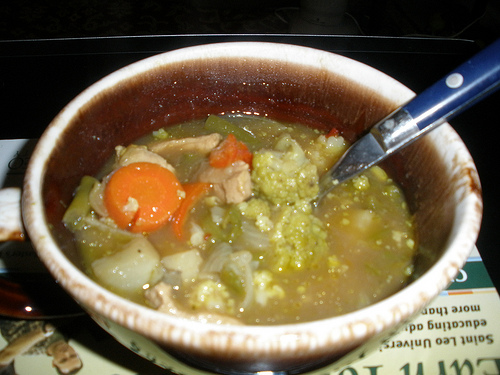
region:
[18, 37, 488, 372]
brown and white ceramic bowl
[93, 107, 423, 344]
vegetable soup in a bowl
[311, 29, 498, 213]
blue spoon in the soup bowl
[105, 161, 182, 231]
orange carrot slice in soup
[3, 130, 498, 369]
magazine underneath soup bowl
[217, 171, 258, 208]
chunk of chicken in soup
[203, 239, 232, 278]
white cooked onion in soup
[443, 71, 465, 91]
decorative silver circle on spoon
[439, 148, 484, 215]
brown streaks in white ceramic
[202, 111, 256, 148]
green bean in soup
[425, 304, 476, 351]
Black colored writings on a newspater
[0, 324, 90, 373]
Picture of a man with short hair on a newspaper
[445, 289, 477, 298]
Brown colored line mark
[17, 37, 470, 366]
Bowl of food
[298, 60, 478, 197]
Spoon inside the bowl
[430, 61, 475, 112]
A white dot on the handle of the spoon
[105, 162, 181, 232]
Piece of carrot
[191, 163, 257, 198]
Piece of meat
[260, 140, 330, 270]
Pieces of vegetable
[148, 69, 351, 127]
Brown colored portion of the bown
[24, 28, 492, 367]
a bowl of soup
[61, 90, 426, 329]
soup of vegetables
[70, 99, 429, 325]
soup is green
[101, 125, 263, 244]
slices of carrot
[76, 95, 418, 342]
soup has carrots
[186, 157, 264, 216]
pieces of meat in soup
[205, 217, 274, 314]
slices of onions in soup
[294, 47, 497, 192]
a spoon in soup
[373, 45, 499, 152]
handle of spoon is blue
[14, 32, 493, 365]
a bowl is brown inside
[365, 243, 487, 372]
a book with green print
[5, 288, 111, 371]
a photograph of a man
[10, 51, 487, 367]
a brown bowl with a white rim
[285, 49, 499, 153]
a spoon with a blue handle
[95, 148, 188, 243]
a round carrot slice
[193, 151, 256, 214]
a piece of stew meat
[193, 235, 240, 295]
cooked onion in stew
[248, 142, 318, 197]
green stained califlower in stew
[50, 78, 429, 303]
a brown stew with vegetables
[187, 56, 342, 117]
condensation on the rim of a soup bowl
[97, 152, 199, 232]
round slice of a carrot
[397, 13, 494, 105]
blue handle of a soup spoon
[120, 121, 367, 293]
soup in a bowl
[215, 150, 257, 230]
chicken chunk in soup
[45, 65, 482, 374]
round brown bowl with soup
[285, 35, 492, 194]
metal spoon in bowl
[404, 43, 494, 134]
blue and silver spoon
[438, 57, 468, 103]
silver rivet in blue handle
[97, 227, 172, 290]
small piece of potato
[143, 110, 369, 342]
soup with carrots and chicken